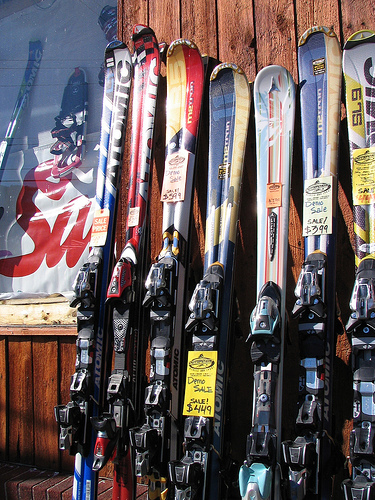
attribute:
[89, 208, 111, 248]
tag — white, red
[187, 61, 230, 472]
matching skis — blue, white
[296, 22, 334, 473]
matching skis — blue, white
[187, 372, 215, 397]
lettering — black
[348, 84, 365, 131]
675 — black, yellow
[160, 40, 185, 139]
ski — yellow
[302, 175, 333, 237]
tag — white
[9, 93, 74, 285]
white sign — red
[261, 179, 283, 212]
price tag — small, orange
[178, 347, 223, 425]
tag — yellow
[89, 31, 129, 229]
ski — yellow, black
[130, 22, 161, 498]
stripes — red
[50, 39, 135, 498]
ski — tall, blue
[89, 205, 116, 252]
price tag — yellow